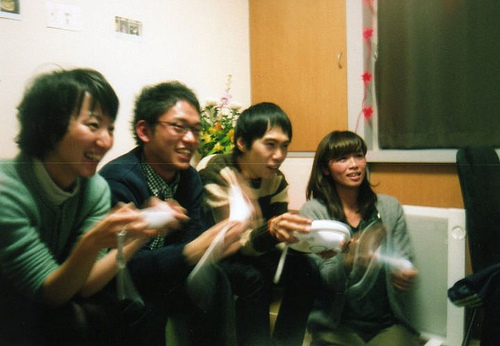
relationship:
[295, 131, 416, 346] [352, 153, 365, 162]
woman has eye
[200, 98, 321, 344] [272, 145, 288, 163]
man has nose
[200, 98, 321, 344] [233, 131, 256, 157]
man has ear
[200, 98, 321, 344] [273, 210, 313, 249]
man has hand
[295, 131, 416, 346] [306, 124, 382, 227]
woman has hair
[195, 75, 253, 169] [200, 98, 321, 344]
flowers behind man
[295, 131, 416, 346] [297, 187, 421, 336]
woman wearing sweater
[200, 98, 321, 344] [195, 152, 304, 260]
man wearing sweater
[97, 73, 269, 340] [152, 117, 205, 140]
man has glasses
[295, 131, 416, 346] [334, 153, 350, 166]
woman has eye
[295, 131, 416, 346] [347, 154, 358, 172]
woman has nose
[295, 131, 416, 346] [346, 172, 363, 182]
woman has mouth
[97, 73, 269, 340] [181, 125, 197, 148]
man has nose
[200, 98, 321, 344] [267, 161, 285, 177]
man has mouth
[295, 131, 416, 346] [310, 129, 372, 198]
woman has head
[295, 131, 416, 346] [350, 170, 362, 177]
woman has teeth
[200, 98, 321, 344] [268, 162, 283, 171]
man has teeth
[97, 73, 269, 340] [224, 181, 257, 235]
man holding wii remote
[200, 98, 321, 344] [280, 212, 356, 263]
man holding wii steering wheel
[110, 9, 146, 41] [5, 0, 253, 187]
picture on wall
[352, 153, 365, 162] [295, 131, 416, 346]
eye of a woman